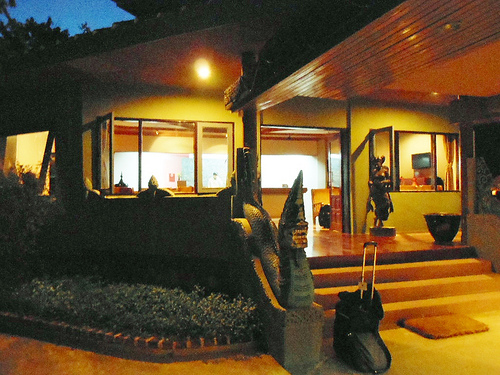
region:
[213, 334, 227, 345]
brick on flower bed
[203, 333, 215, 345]
brick on flower bed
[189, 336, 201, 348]
brick on flower bed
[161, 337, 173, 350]
brick on flower bed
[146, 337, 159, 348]
brick on flower bed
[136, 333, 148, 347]
brick on flower bed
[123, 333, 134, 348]
brick on flower bed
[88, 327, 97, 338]
brick on flower bed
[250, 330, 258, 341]
brick on flower bed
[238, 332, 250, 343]
brick on flower bed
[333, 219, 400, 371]
The suitcase is sitting on the ground.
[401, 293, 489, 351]
The mat is beside the steps.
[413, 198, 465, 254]
The flower pot is empty.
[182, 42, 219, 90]
The light is lit.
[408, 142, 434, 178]
The TV is on.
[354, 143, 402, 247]
The statue is on the porch.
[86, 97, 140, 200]
The window is open.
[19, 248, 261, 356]
The shrubbery is green.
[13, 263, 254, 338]
The shrubbery is well maintained.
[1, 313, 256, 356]
The flower bed is outlined with bricks.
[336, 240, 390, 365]
a suitcase on the ground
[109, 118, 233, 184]
windows on the house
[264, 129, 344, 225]
the doorway of the house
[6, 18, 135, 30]
the sky behind the tree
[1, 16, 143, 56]
a tree behind the house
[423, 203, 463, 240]
a pot on the porch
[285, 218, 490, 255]
the porch of the house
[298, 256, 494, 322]
stairs in front of the house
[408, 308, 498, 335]
a rug on the ground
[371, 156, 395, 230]
a statue on the porch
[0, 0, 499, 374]
A brightly lit home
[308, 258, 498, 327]
The front door steps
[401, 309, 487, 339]
A flat door mat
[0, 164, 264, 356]
The green flower garden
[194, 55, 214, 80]
A bright ceiling light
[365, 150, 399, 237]
A human figure statue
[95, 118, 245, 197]
The opened windows on the left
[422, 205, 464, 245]
The dark flower pot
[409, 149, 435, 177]
The television set inside the house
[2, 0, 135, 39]
The blue sky on the left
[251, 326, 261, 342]
brick of flower bed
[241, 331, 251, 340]
brick of flower bed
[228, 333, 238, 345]
brick of flower bed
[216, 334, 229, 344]
brick of flower bed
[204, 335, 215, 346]
brick of flower bed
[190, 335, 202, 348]
brick of flower bed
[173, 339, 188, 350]
brick of flower bed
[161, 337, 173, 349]
brick of flower bed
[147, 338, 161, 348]
brick of flower bed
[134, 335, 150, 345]
brick of flower bed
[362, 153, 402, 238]
statue stands by door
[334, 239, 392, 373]
suitcase stands at bottom of stairs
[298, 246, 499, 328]
stairs behind suitcase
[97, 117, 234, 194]
window on side of house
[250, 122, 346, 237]
doorway is open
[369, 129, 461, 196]
window on side of house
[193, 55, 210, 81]
light is turned on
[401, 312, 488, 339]
welcome mat at bottom of stairs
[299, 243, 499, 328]
stairs behind welcome mat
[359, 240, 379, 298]
handle is extended